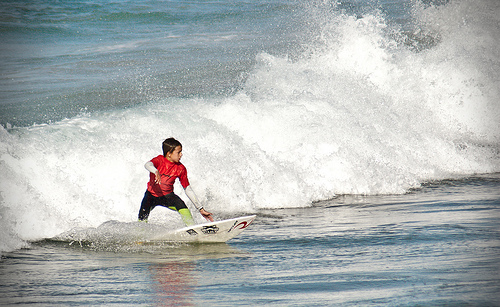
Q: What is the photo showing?
A: It is showing an ocean.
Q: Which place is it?
A: It is an ocean.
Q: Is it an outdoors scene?
A: Yes, it is outdoors.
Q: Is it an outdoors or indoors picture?
A: It is outdoors.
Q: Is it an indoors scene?
A: No, it is outdoors.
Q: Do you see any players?
A: No, there are no players.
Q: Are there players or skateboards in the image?
A: No, there are no players or skateboards.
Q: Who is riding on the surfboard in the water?
A: The boy is riding on the surfboard.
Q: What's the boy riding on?
A: The boy is riding on the surfboard.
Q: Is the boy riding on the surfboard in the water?
A: Yes, the boy is riding on the surfboard.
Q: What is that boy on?
A: The boy is on the surfboard.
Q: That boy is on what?
A: The boy is on the surfboard.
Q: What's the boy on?
A: The boy is on the surfboard.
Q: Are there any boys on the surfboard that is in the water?
A: Yes, there is a boy on the surfboard.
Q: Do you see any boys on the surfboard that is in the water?
A: Yes, there is a boy on the surfboard.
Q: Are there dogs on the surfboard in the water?
A: No, there is a boy on the surfboard.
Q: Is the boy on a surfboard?
A: Yes, the boy is on a surfboard.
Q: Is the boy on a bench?
A: No, the boy is on a surfboard.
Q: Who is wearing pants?
A: The boy is wearing pants.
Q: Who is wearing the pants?
A: The boy is wearing pants.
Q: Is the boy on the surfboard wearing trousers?
A: Yes, the boy is wearing trousers.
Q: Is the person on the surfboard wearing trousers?
A: Yes, the boy is wearing trousers.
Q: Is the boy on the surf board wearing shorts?
A: No, the boy is wearing trousers.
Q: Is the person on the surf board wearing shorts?
A: No, the boy is wearing trousers.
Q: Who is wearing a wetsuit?
A: The boy is wearing a wetsuit.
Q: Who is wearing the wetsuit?
A: The boy is wearing a wetsuit.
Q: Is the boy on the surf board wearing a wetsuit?
A: Yes, the boy is wearing a wetsuit.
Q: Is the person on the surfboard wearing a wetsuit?
A: Yes, the boy is wearing a wetsuit.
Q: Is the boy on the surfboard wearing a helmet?
A: No, the boy is wearing a wetsuit.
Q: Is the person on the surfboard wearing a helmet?
A: No, the boy is wearing a wetsuit.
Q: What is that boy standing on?
A: The boy is standing on the surfboard.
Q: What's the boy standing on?
A: The boy is standing on the surfboard.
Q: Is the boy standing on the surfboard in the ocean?
A: Yes, the boy is standing on the surfboard.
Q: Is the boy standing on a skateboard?
A: No, the boy is standing on the surfboard.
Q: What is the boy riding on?
A: The boy is riding on the surf board.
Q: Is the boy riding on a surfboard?
A: Yes, the boy is riding on a surfboard.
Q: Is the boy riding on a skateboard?
A: No, the boy is riding on a surfboard.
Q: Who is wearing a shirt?
A: The boy is wearing a shirt.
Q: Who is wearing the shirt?
A: The boy is wearing a shirt.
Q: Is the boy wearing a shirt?
A: Yes, the boy is wearing a shirt.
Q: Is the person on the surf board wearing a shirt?
A: Yes, the boy is wearing a shirt.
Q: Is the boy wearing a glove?
A: No, the boy is wearing a shirt.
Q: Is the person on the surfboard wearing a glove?
A: No, the boy is wearing a shirt.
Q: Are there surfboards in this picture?
A: Yes, there is a surfboard.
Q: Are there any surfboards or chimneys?
A: Yes, there is a surfboard.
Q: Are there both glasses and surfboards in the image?
A: No, there is a surfboard but no glasses.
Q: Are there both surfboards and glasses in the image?
A: No, there is a surfboard but no glasses.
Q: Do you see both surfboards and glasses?
A: No, there is a surfboard but no glasses.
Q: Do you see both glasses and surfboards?
A: No, there is a surfboard but no glasses.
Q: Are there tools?
A: No, there are no tools.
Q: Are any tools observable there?
A: No, there are no tools.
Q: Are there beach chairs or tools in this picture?
A: No, there are no tools or beach chairs.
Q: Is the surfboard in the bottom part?
A: Yes, the surfboard is in the bottom of the image.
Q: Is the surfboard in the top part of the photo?
A: No, the surfboard is in the bottom of the image.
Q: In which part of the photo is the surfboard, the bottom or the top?
A: The surfboard is in the bottom of the image.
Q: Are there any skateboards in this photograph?
A: No, there are no skateboards.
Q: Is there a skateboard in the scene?
A: No, there are no skateboards.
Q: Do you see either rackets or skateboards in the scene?
A: No, there are no skateboards or rackets.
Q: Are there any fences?
A: No, there are no fences.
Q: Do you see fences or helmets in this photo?
A: No, there are no fences or helmets.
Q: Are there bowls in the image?
A: No, there are no bowls.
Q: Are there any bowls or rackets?
A: No, there are no bowls or rackets.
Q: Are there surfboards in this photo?
A: Yes, there is a surfboard.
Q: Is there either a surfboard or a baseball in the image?
A: Yes, there is a surfboard.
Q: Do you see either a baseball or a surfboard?
A: Yes, there is a surfboard.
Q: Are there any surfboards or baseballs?
A: Yes, there is a surfboard.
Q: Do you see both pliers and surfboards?
A: No, there is a surfboard but no pliers.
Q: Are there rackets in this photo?
A: No, there are no rackets.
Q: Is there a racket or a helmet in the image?
A: No, there are no rackets or helmets.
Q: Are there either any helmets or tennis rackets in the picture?
A: No, there are no tennis rackets or helmets.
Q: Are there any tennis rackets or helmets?
A: No, there are no tennis rackets or helmets.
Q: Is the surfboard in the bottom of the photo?
A: Yes, the surfboard is in the bottom of the image.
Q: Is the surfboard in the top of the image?
A: No, the surfboard is in the bottom of the image.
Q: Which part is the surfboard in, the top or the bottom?
A: The surfboard is in the bottom of the image.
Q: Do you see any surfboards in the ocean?
A: Yes, there is a surfboard in the ocean.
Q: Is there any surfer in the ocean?
A: No, there is a surfboard in the ocean.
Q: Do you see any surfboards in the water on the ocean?
A: Yes, there is a surfboard in the water.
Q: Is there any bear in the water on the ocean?
A: No, there is a surfboard in the water.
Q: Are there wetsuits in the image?
A: Yes, there is a wetsuit.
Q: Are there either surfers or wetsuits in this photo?
A: Yes, there is a wetsuit.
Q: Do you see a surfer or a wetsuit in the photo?
A: Yes, there is a wetsuit.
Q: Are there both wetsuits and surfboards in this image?
A: Yes, there are both a wetsuit and a surfboard.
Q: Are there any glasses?
A: No, there are no glasses.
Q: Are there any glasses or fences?
A: No, there are no glasses or fences.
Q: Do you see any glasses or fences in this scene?
A: No, there are no glasses or fences.